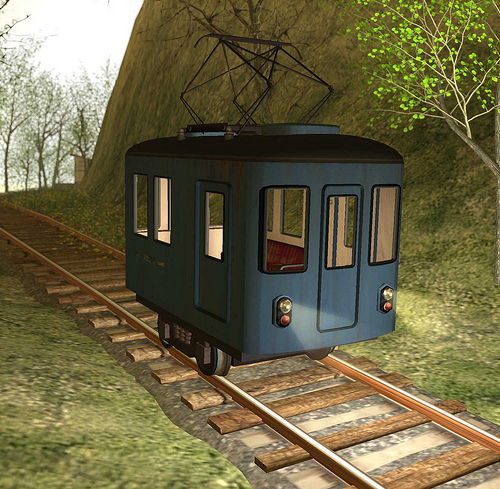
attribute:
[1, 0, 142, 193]
sky — cloudy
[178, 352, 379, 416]
slat — wooden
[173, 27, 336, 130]
structure — black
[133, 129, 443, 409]
train — cart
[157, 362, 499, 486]
tracks — brown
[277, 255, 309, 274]
railing — metal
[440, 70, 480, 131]
branch — brown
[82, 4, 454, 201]
wall — rocky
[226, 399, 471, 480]
bar — wooden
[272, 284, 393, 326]
lights — on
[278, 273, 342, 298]
light — red, white